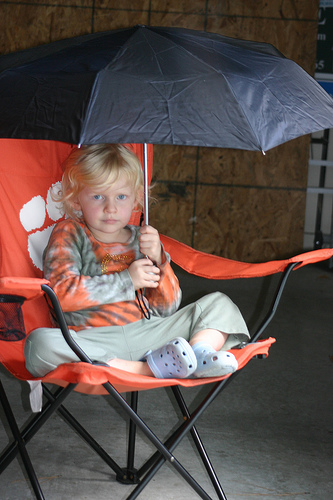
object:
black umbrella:
[3, 29, 332, 156]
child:
[24, 143, 250, 379]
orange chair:
[0, 137, 331, 500]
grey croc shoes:
[145, 337, 197, 378]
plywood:
[3, 6, 316, 269]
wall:
[3, 3, 321, 271]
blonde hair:
[61, 145, 151, 222]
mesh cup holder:
[0, 292, 27, 341]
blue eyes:
[93, 193, 104, 200]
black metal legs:
[124, 259, 304, 500]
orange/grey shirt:
[41, 218, 182, 332]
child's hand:
[137, 220, 160, 262]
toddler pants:
[24, 291, 253, 379]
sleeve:
[43, 221, 137, 308]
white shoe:
[190, 345, 238, 379]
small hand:
[125, 259, 161, 290]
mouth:
[100, 218, 119, 225]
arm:
[149, 260, 182, 316]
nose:
[106, 197, 117, 213]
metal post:
[143, 144, 149, 286]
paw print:
[17, 180, 72, 273]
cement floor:
[3, 259, 329, 500]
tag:
[26, 378, 44, 415]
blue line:
[152, 179, 307, 192]